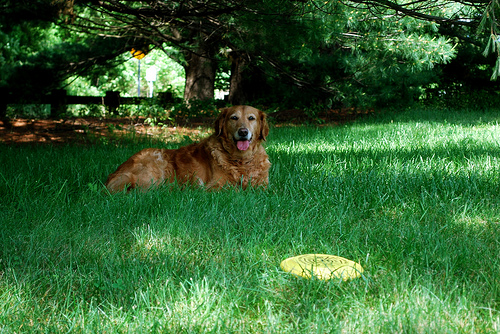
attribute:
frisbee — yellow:
[279, 252, 365, 280]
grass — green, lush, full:
[0, 106, 499, 333]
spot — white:
[265, 122, 500, 150]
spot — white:
[338, 286, 499, 332]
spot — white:
[1, 268, 309, 334]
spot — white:
[132, 224, 178, 251]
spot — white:
[451, 205, 489, 230]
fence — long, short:
[1, 83, 229, 116]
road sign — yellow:
[130, 47, 145, 59]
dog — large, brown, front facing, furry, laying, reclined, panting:
[104, 104, 273, 195]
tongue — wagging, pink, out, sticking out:
[236, 139, 251, 152]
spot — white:
[152, 148, 163, 161]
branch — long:
[378, 1, 499, 28]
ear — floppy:
[260, 109, 268, 140]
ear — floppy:
[214, 107, 228, 137]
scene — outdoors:
[0, 1, 497, 334]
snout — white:
[234, 125, 253, 141]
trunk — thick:
[185, 46, 215, 99]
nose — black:
[237, 128, 249, 135]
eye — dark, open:
[247, 115, 254, 121]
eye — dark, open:
[228, 114, 239, 121]